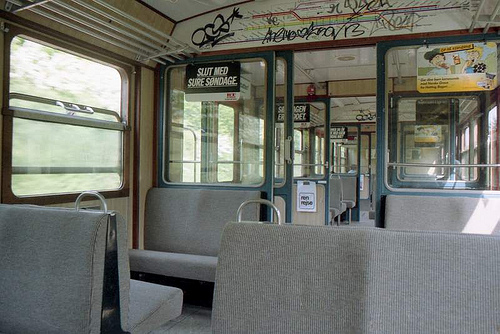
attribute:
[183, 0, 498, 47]
wall —  with map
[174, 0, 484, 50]
wall —  with map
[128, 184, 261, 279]
bench — of fabric,  gray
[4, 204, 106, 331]
bench —  gray, of fabric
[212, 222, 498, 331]
bench — of fabric,  gray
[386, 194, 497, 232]
bench — of fabric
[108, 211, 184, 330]
bench —  of fabric,  gray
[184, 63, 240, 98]
sign — colored, white, ther, advert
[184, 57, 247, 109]
paper — colored, sticked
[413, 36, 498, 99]
advert — colored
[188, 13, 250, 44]
graffiti — writtwn, written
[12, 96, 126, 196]
window — open, clear , closed,  open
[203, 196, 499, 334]
seat — fabric , gray , grey,  gray,  of   transit bus , of transit bus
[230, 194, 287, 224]
handle — metallic, circular, sillver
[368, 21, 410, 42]
tagging — done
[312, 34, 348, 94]
map — of train station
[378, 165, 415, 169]
pipe — white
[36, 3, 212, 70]
rack — attached